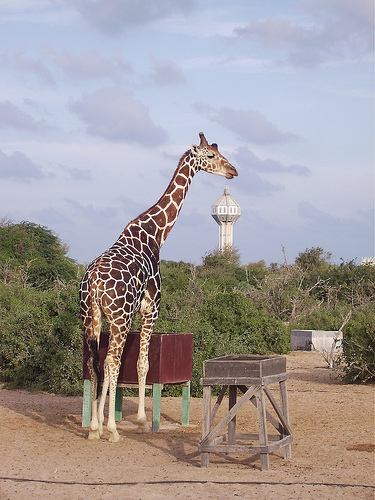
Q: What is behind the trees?
A: A tower.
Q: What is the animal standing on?
A: Sand.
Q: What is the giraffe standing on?
A: Sand.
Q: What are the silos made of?
A: Wood.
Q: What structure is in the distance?
A: A tower.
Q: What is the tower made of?
A: Concrete.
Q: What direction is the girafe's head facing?
A: Right.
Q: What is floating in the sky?
A: Clouds.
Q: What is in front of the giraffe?
A: A wooden silo.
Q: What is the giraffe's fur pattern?
A: Mosaic.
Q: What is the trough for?
A: Feeding.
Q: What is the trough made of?
A: Wood.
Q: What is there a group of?
A: Trees.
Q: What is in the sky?
A: Clouds.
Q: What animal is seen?
A: Giraffe.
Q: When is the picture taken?
A: Daytime.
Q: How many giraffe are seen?
A: 1.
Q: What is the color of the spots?
A: Brown.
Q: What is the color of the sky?
A: Blue.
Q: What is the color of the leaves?
A: Green.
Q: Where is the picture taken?
A: Animal habitat.